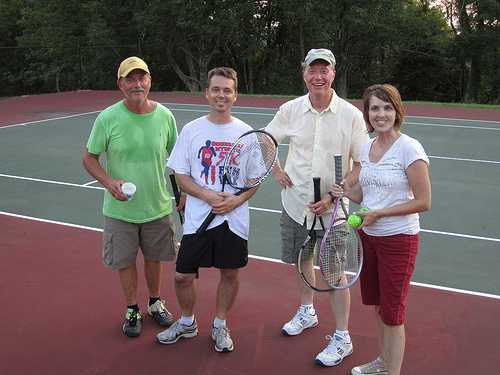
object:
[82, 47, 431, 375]
people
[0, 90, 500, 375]
tennis court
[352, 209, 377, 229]
hand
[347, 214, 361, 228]
tennis ball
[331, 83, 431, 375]
woman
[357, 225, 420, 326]
shorts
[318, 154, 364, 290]
racket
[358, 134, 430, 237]
top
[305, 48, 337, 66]
hat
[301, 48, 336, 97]
head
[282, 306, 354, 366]
shoes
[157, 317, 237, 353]
shoes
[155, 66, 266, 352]
man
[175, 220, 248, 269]
shorts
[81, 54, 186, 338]
man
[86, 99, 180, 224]
shirt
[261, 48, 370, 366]
man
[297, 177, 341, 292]
racket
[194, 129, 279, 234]
racket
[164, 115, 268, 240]
shirt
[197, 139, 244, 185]
advertisement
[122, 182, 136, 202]
cup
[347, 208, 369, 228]
tennis balls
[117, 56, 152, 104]
head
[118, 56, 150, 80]
hat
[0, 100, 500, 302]
lines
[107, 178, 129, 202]
hand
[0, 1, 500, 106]
trees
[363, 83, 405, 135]
hair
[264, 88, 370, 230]
shirt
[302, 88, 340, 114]
collar